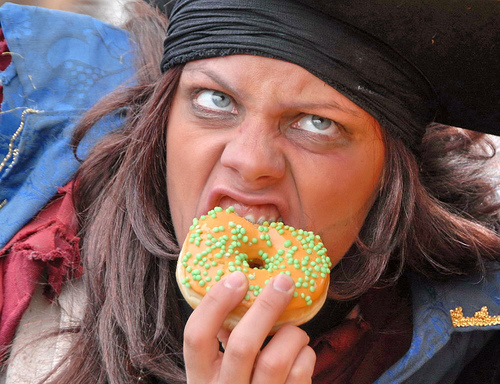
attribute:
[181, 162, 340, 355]
donut — round, brown, beige, soft, good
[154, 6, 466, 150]
tavern — black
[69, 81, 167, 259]
hair — brown, red, dark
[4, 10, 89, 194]
cloth — blue, red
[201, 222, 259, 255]
sprinkles — green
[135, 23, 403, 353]
woman — eating, enjoying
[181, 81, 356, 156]
eyes — blue, gray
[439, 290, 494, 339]
design — gold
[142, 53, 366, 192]
skin — brown, tan